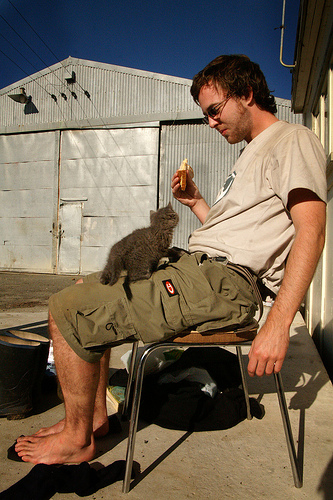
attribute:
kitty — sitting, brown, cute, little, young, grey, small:
[104, 216, 184, 278]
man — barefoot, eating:
[46, 54, 307, 486]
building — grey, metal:
[1, 50, 273, 281]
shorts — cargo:
[37, 237, 262, 339]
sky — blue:
[6, 2, 258, 59]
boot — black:
[3, 314, 49, 418]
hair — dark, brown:
[188, 46, 277, 112]